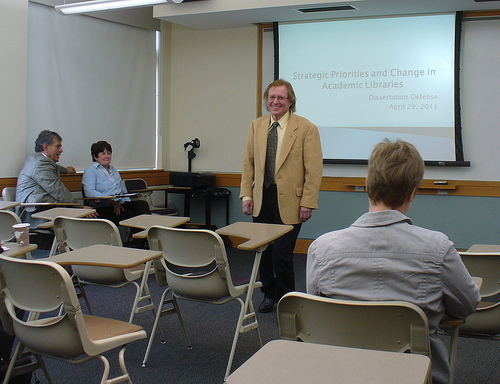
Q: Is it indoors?
A: Yes, it is indoors.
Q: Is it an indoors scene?
A: Yes, it is indoors.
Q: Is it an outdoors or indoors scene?
A: It is indoors.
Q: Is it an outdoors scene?
A: No, it is indoors.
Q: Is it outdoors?
A: No, it is indoors.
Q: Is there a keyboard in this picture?
A: No, there are no keyboards.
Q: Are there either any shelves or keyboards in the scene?
A: No, there are no keyboards or shelves.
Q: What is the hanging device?
A: The device is a screen.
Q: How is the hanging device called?
A: The device is a screen.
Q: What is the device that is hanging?
A: The device is a screen.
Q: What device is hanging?
A: The device is a screen.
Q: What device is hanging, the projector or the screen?
A: The screen is hanging.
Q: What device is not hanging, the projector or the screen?
A: The projector is not hanging.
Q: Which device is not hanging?
A: The device is a projector.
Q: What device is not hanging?
A: The device is a projector.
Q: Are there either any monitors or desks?
A: Yes, there is a desk.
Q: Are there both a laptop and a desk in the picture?
A: No, there is a desk but no laptops.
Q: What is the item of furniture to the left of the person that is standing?
A: The piece of furniture is a desk.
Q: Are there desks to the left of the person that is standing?
A: Yes, there is a desk to the left of the person.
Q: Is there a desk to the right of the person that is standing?
A: No, the desk is to the left of the person.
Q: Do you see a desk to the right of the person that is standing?
A: No, the desk is to the left of the person.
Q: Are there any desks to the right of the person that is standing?
A: No, the desk is to the left of the person.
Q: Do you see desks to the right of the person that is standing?
A: No, the desk is to the left of the person.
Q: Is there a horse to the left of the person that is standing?
A: No, there is a desk to the left of the person.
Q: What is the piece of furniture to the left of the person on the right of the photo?
A: The piece of furniture is a desk.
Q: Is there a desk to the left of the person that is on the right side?
A: Yes, there is a desk to the left of the person.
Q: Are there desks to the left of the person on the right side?
A: Yes, there is a desk to the left of the person.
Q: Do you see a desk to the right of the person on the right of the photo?
A: No, the desk is to the left of the person.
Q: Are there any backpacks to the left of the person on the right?
A: No, there is a desk to the left of the person.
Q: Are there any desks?
A: Yes, there is a desk.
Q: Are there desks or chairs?
A: Yes, there is a desk.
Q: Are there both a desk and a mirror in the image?
A: No, there is a desk but no mirrors.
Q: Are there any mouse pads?
A: No, there are no mouse pads.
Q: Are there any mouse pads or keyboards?
A: No, there are no mouse pads or keyboards.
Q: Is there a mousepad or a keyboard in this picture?
A: No, there are no mouse pads or keyboards.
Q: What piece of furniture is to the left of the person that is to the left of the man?
A: The piece of furniture is a desk.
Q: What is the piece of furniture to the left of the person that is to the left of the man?
A: The piece of furniture is a desk.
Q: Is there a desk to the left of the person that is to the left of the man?
A: Yes, there is a desk to the left of the person.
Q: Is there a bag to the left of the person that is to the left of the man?
A: No, there is a desk to the left of the person.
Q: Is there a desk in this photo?
A: Yes, there is a desk.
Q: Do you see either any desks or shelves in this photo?
A: Yes, there is a desk.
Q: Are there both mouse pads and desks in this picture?
A: No, there is a desk but no mouse pads.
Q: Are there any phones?
A: No, there are no phones.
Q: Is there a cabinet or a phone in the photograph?
A: No, there are no phones or cabinets.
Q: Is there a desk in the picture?
A: Yes, there is a desk.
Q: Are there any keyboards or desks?
A: Yes, there is a desk.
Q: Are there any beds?
A: No, there are no beds.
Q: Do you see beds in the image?
A: No, there are no beds.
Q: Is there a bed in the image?
A: No, there are no beds.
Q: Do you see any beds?
A: No, there are no beds.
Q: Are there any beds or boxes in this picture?
A: No, there are no beds or boxes.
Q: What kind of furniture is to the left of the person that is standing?
A: The piece of furniture is a desk.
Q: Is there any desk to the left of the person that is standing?
A: Yes, there is a desk to the left of the person.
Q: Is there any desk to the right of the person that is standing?
A: No, the desk is to the left of the person.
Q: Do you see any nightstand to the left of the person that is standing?
A: No, there is a desk to the left of the person.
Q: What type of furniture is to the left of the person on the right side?
A: The piece of furniture is a desk.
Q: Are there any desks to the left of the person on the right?
A: Yes, there is a desk to the left of the person.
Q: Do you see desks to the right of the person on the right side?
A: No, the desk is to the left of the person.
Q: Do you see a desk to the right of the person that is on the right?
A: No, the desk is to the left of the person.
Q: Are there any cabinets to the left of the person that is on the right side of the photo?
A: No, there is a desk to the left of the person.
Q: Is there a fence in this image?
A: No, there are no fences.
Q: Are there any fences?
A: No, there are no fences.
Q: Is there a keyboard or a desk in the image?
A: Yes, there is a desk.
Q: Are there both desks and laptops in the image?
A: No, there is a desk but no laptops.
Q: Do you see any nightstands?
A: No, there are no nightstands.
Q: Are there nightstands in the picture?
A: No, there are no nightstands.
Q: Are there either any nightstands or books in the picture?
A: No, there are no nightstands or books.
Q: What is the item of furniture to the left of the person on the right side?
A: The piece of furniture is a desk.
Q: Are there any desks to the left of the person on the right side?
A: Yes, there is a desk to the left of the person.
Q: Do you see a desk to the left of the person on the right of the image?
A: Yes, there is a desk to the left of the person.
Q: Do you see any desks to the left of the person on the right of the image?
A: Yes, there is a desk to the left of the person.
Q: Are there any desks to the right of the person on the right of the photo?
A: No, the desk is to the left of the person.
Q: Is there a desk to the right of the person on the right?
A: No, the desk is to the left of the person.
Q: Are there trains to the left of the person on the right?
A: No, there is a desk to the left of the person.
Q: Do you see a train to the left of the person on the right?
A: No, there is a desk to the left of the person.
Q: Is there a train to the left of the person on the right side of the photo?
A: No, there is a desk to the left of the person.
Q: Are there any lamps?
A: No, there are no lamps.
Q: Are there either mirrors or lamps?
A: No, there are no lamps or mirrors.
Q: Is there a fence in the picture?
A: No, there are no fences.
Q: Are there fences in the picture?
A: No, there are no fences.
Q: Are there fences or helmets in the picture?
A: No, there are no fences or helmets.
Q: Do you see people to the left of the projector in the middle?
A: Yes, there is a person to the left of the projector.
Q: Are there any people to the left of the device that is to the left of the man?
A: Yes, there is a person to the left of the projector.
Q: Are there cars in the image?
A: No, there are no cars.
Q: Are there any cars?
A: No, there are no cars.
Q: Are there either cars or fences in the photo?
A: No, there are no cars or fences.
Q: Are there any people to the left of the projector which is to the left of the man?
A: Yes, there is a person to the left of the projector.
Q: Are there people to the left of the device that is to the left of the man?
A: Yes, there is a person to the left of the projector.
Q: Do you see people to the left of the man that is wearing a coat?
A: Yes, there is a person to the left of the man.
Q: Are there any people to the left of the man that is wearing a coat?
A: Yes, there is a person to the left of the man.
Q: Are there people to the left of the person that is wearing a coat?
A: Yes, there is a person to the left of the man.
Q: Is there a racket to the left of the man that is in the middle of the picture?
A: No, there is a person to the left of the man.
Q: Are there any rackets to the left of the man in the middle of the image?
A: No, there is a person to the left of the man.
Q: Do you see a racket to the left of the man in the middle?
A: No, there is a person to the left of the man.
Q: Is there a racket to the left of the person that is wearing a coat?
A: No, there is a person to the left of the man.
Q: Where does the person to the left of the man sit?
A: The person sits at the desk.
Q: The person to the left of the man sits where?
A: The person sits at the desk.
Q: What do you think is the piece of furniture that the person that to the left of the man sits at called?
A: The piece of furniture is a desk.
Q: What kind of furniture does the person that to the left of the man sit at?
A: The person sits at the desk.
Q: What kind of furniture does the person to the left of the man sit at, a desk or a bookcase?
A: The person sits at a desk.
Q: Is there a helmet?
A: No, there are no helmets.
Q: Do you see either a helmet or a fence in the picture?
A: No, there are no helmets or fences.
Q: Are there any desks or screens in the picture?
A: Yes, there is a desk.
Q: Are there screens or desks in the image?
A: Yes, there is a desk.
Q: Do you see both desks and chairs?
A: Yes, there are both a desk and a chair.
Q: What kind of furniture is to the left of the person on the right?
A: The piece of furniture is a desk.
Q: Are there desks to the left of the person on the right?
A: Yes, there is a desk to the left of the person.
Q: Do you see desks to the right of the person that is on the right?
A: No, the desk is to the left of the person.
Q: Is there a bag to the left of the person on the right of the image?
A: No, there is a desk to the left of the person.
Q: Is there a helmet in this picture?
A: No, there are no helmets.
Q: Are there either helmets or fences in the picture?
A: No, there are no helmets or fences.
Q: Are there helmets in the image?
A: No, there are no helmets.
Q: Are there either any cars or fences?
A: No, there are no cars or fences.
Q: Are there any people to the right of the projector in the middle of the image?
A: Yes, there is a person to the right of the projector.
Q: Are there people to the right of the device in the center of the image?
A: Yes, there is a person to the right of the projector.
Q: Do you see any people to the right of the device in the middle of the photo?
A: Yes, there is a person to the right of the projector.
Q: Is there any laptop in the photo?
A: No, there are no laptops.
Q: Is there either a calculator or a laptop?
A: No, there are no laptops or calculators.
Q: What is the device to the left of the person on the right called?
A: The device is a projector.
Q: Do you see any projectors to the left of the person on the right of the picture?
A: Yes, there is a projector to the left of the person.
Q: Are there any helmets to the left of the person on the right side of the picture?
A: No, there is a projector to the left of the person.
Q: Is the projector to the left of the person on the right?
A: Yes, the projector is to the left of the person.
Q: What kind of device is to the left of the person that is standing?
A: The device is a projector.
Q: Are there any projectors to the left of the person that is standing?
A: Yes, there is a projector to the left of the person.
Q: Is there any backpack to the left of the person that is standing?
A: No, there is a projector to the left of the person.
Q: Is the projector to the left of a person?
A: Yes, the projector is to the left of a person.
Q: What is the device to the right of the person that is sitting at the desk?
A: The device is a projector.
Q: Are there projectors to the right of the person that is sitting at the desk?
A: Yes, there is a projector to the right of the person.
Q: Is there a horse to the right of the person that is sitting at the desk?
A: No, there is a projector to the right of the person.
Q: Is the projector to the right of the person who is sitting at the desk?
A: Yes, the projector is to the right of the person.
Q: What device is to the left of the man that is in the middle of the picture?
A: The device is a projector.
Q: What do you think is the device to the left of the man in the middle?
A: The device is a projector.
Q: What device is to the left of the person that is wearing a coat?
A: The device is a projector.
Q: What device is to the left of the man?
A: The device is a projector.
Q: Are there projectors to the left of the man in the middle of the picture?
A: Yes, there is a projector to the left of the man.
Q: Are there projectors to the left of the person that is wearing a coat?
A: Yes, there is a projector to the left of the man.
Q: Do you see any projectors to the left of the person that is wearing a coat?
A: Yes, there is a projector to the left of the man.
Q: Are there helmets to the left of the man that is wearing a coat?
A: No, there is a projector to the left of the man.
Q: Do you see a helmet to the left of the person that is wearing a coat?
A: No, there is a projector to the left of the man.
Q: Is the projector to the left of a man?
A: Yes, the projector is to the left of a man.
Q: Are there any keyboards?
A: No, there are no keyboards.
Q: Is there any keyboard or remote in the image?
A: No, there are no keyboards or remote controls.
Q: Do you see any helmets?
A: No, there are no helmets.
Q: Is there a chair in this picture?
A: Yes, there is a chair.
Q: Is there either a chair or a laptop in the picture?
A: Yes, there is a chair.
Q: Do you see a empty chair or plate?
A: Yes, there is an empty chair.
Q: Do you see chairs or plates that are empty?
A: Yes, the chair is empty.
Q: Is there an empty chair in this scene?
A: Yes, there is an empty chair.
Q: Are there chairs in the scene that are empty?
A: Yes, there is a chair that is empty.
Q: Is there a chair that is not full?
A: Yes, there is a empty chair.